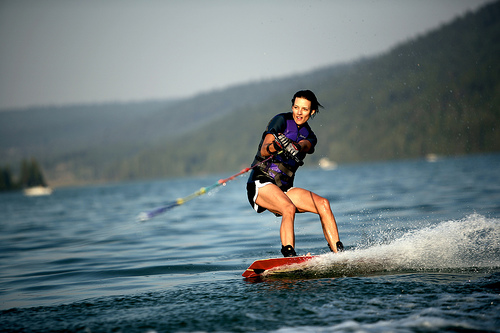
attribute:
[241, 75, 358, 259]
woman — waterskiing, waterboarding, here, light-skinned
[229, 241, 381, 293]
ski board — red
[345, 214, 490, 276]
water — here, calm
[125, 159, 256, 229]
tether rope — colorful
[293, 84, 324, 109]
hair — dark brown, black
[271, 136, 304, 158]
gloves — black, white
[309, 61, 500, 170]
trees — evergreen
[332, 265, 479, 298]
wave — white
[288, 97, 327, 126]
woman's face — smiling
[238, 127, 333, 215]
suit — black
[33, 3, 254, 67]
clouds — white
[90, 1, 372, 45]
sky — blue, here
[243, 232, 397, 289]
surfboard — here, red